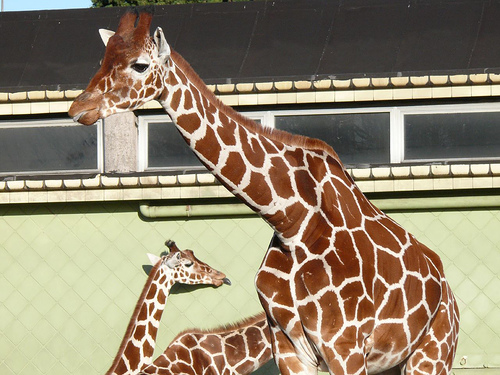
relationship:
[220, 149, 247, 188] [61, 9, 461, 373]
spot on giraffe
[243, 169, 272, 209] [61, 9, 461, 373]
spot on giraffe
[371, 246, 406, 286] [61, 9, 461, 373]
spot on giraffe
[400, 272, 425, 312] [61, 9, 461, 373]
spot on giraffe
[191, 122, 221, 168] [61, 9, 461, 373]
spot on giraffe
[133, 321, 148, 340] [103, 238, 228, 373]
spot on giraffe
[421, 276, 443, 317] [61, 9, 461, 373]
spot on giraffe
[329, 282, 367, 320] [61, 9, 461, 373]
spot on giraffe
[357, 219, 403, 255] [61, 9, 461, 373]
spot on giraffe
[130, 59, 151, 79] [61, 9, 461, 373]
eye on giraffe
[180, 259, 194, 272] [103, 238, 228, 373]
eye on giraffe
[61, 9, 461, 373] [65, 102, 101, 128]
giraffe has mouth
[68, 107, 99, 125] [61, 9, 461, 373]
mouth on giraffe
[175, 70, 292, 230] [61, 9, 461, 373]
neck on giraffe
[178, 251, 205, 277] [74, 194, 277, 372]
eye on giraffe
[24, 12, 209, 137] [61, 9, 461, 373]
head on giraffe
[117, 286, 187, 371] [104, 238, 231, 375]
neck on giraffe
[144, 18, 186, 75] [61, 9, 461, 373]
ear on giraffe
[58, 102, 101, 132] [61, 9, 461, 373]
tongue on giraffe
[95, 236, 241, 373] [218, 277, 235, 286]
giraffe sticking out tongue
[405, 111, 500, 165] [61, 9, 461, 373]
window behind giraffe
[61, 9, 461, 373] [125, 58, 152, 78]
giraffe has eye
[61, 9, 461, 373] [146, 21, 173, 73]
giraffe has ear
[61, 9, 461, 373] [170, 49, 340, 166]
giraffe has mane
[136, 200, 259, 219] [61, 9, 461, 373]
pipe above giraffe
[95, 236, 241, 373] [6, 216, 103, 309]
giraffe in front of tile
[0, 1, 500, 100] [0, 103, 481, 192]
roof above windows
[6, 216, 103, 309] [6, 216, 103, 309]
tile in tile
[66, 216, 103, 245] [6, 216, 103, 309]
tile in tile